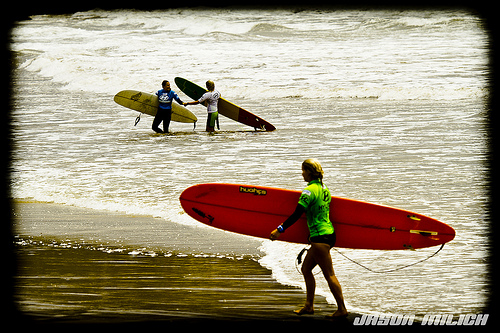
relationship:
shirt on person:
[297, 179, 336, 239] [267, 158, 349, 318]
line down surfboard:
[177, 191, 459, 242] [172, 178, 459, 258]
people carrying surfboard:
[149, 79, 186, 134] [114, 87, 198, 124]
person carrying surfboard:
[183, 80, 221, 132] [172, 77, 276, 133]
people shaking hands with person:
[149, 79, 186, 134] [183, 80, 222, 132]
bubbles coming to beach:
[31, 36, 498, 285] [11, 97, 489, 325]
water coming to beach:
[16, 10, 487, 325] [11, 97, 489, 325]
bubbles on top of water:
[31, 36, 498, 285] [16, 10, 487, 325]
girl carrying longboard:
[266, 158, 348, 319] [178, 183, 454, 252]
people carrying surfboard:
[149, 79, 186, 134] [112, 88, 198, 130]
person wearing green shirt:
[267, 158, 349, 318] [294, 179, 333, 239]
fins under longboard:
[411, 230, 439, 236] [178, 183, 454, 252]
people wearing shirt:
[149, 79, 186, 134] [151, 99, 211, 124]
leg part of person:
[310, 241, 350, 319] [267, 158, 349, 318]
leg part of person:
[290, 249, 319, 316] [267, 158, 349, 318]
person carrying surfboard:
[267, 158, 349, 318] [172, 178, 459, 258]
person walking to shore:
[267, 158, 349, 318] [13, 51, 361, 317]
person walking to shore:
[183, 80, 221, 132] [13, 51, 361, 317]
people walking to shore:
[149, 79, 186, 134] [13, 51, 361, 317]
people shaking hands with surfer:
[149, 79, 186, 134] [183, 78, 219, 132]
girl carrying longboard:
[264, 154, 352, 320] [176, 179, 458, 248]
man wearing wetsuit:
[155, 78, 189, 138] [152, 90, 183, 132]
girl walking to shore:
[266, 158, 348, 319] [32, 204, 160, 300]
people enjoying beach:
[149, 79, 186, 134] [11, 51, 362, 313]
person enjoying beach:
[183, 80, 222, 132] [11, 51, 362, 313]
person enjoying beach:
[267, 158, 349, 318] [11, 51, 362, 313]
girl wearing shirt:
[266, 158, 348, 319] [297, 179, 336, 239]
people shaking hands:
[149, 78, 224, 138] [180, 100, 191, 108]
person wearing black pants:
[267, 158, 349, 318] [150, 107, 174, 134]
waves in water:
[83, 19, 429, 41] [8, 10, 487, 326]